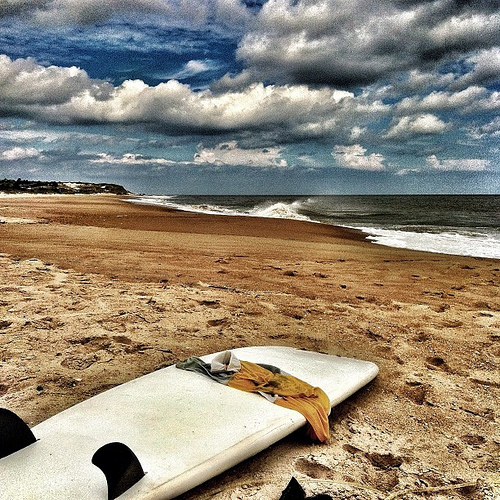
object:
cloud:
[42, 70, 372, 157]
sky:
[0, 2, 500, 195]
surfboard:
[2, 343, 378, 500]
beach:
[0, 193, 495, 495]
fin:
[89, 438, 146, 499]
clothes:
[175, 344, 338, 442]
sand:
[0, 206, 499, 499]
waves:
[143, 191, 332, 228]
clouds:
[231, 2, 496, 150]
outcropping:
[5, 176, 128, 199]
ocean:
[134, 191, 500, 259]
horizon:
[127, 191, 499, 195]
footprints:
[427, 299, 451, 314]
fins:
[0, 406, 37, 460]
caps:
[260, 198, 303, 211]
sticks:
[126, 343, 173, 358]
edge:
[341, 362, 383, 397]